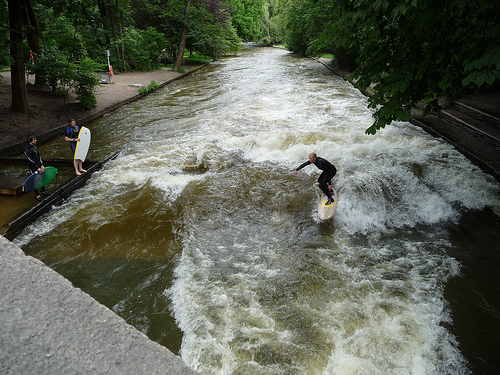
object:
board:
[73, 124, 92, 162]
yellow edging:
[74, 126, 84, 160]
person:
[64, 117, 88, 177]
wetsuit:
[62, 125, 84, 156]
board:
[22, 165, 60, 192]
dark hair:
[26, 135, 36, 145]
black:
[68, 132, 78, 137]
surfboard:
[316, 185, 338, 222]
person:
[289, 149, 339, 205]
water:
[0, 42, 499, 375]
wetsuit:
[295, 156, 338, 198]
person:
[22, 133, 48, 202]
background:
[1, 1, 500, 137]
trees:
[155, 0, 238, 74]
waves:
[248, 114, 355, 156]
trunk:
[5, 1, 39, 121]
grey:
[317, 185, 337, 221]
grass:
[138, 77, 162, 95]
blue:
[65, 126, 74, 134]